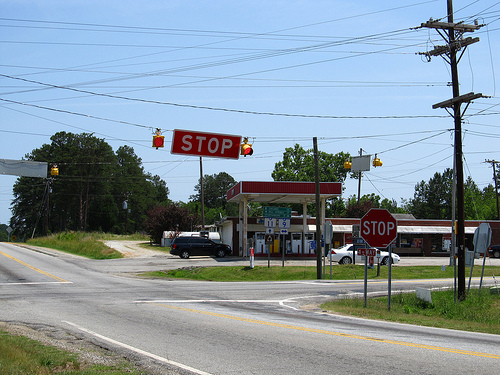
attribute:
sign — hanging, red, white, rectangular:
[169, 128, 243, 163]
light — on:
[242, 144, 254, 158]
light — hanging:
[151, 131, 167, 149]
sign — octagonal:
[358, 207, 399, 249]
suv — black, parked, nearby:
[168, 234, 231, 261]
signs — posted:
[262, 204, 293, 237]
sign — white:
[264, 217, 278, 230]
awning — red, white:
[225, 179, 344, 206]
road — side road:
[100, 236, 176, 260]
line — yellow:
[1, 249, 66, 283]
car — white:
[325, 240, 404, 267]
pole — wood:
[311, 135, 323, 282]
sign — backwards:
[1, 157, 49, 181]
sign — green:
[261, 204, 294, 222]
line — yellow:
[159, 299, 498, 362]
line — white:
[130, 296, 281, 307]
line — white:
[1, 280, 73, 288]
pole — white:
[247, 244, 257, 271]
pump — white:
[288, 230, 304, 255]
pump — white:
[303, 231, 316, 256]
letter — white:
[179, 132, 194, 153]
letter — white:
[193, 131, 208, 155]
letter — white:
[206, 135, 222, 156]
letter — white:
[219, 135, 233, 157]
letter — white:
[361, 218, 373, 237]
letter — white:
[369, 219, 379, 238]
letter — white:
[375, 218, 387, 238]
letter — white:
[384, 220, 395, 240]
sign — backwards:
[471, 220, 495, 256]